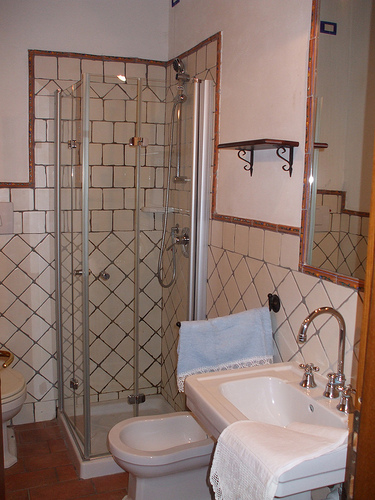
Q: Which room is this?
A: It is a bathroom.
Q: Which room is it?
A: It is a bathroom.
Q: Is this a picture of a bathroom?
A: Yes, it is showing a bathroom.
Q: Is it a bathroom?
A: Yes, it is a bathroom.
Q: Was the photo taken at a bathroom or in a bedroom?
A: It was taken at a bathroom.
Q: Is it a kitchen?
A: No, it is a bathroom.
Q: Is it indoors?
A: Yes, it is indoors.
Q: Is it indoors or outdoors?
A: It is indoors.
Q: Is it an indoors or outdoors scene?
A: It is indoors.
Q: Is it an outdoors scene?
A: No, it is indoors.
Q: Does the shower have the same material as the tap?
A: No, the shower is made of glass and the tap is made of metal.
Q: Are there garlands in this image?
A: No, there are no garlands.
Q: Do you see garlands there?
A: No, there are no garlands.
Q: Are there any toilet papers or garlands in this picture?
A: No, there are no garlands or toilet papers.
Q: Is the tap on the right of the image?
A: Yes, the tap is on the right of the image.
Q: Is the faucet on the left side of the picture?
A: No, the faucet is on the right of the image.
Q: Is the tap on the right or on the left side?
A: The tap is on the right of the image.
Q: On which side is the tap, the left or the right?
A: The tap is on the right of the image.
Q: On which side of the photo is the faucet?
A: The faucet is on the right of the image.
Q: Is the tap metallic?
A: Yes, the tap is metallic.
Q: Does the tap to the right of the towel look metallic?
A: Yes, the tap is metallic.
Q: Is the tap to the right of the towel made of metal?
A: Yes, the tap is made of metal.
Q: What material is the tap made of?
A: The tap is made of metal.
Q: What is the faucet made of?
A: The tap is made of metal.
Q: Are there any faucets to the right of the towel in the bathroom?
A: Yes, there is a faucet to the right of the towel.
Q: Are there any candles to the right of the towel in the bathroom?
A: No, there is a faucet to the right of the towel.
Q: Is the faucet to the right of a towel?
A: Yes, the faucet is to the right of a towel.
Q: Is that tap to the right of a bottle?
A: No, the tap is to the right of a towel.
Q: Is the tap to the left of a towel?
A: No, the tap is to the right of a towel.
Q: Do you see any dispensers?
A: No, there are no dispensers.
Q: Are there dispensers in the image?
A: No, there are no dispensers.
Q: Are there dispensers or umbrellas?
A: No, there are no dispensers or umbrellas.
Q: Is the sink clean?
A: Yes, the sink is clean.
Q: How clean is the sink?
A: The sink is clean.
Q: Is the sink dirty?
A: No, the sink is clean.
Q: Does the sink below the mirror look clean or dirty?
A: The sink is clean.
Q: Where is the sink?
A: The sink is in the bathroom.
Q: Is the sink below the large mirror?
A: Yes, the sink is below the mirror.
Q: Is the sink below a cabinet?
A: No, the sink is below the mirror.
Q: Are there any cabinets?
A: No, there are no cabinets.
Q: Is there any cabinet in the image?
A: No, there are no cabinets.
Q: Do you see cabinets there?
A: No, there are no cabinets.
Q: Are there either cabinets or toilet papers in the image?
A: No, there are no cabinets or toilet papers.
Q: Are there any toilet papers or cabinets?
A: No, there are no cabinets or toilet papers.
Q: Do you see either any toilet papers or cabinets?
A: No, there are no cabinets or toilet papers.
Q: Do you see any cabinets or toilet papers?
A: No, there are no cabinets or toilet papers.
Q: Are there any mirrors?
A: Yes, there is a mirror.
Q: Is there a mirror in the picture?
A: Yes, there is a mirror.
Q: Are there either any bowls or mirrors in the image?
A: Yes, there is a mirror.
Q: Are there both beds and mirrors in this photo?
A: No, there is a mirror but no beds.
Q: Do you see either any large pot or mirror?
A: Yes, there is a large mirror.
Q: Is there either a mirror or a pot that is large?
A: Yes, the mirror is large.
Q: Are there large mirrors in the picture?
A: Yes, there is a large mirror.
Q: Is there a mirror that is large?
A: Yes, there is a mirror that is large.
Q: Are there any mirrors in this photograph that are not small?
A: Yes, there is a large mirror.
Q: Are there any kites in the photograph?
A: No, there are no kites.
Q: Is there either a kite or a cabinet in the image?
A: No, there are no kites or cabinets.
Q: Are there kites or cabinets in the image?
A: No, there are no kites or cabinets.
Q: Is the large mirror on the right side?
A: Yes, the mirror is on the right of the image.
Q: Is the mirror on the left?
A: No, the mirror is on the right of the image.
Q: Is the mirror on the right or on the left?
A: The mirror is on the right of the image.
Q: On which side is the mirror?
A: The mirror is on the right of the image.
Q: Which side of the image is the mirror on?
A: The mirror is on the right of the image.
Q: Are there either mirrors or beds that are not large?
A: No, there is a mirror but it is large.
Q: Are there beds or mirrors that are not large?
A: No, there is a mirror but it is large.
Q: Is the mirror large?
A: Yes, the mirror is large.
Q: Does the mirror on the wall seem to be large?
A: Yes, the mirror is large.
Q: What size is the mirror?
A: The mirror is large.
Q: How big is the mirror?
A: The mirror is large.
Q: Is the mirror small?
A: No, the mirror is large.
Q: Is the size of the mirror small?
A: No, the mirror is large.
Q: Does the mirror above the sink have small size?
A: No, the mirror is large.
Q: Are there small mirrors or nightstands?
A: No, there is a mirror but it is large.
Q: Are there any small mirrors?
A: No, there is a mirror but it is large.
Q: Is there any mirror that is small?
A: No, there is a mirror but it is large.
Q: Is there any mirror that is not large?
A: No, there is a mirror but it is large.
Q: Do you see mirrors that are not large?
A: No, there is a mirror but it is large.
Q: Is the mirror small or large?
A: The mirror is large.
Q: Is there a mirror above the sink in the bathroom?
A: Yes, there is a mirror above the sink.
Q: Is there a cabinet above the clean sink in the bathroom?
A: No, there is a mirror above the sink.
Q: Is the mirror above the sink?
A: Yes, the mirror is above the sink.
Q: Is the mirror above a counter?
A: No, the mirror is above the sink.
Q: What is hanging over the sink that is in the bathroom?
A: The mirror is hanging over the sink.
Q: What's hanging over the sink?
A: The mirror is hanging over the sink.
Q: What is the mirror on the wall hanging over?
A: The mirror is hanging over the sink.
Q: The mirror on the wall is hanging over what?
A: The mirror is hanging over the sink.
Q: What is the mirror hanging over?
A: The mirror is hanging over the sink.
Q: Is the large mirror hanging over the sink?
A: Yes, the mirror is hanging over the sink.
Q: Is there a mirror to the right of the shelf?
A: Yes, there is a mirror to the right of the shelf.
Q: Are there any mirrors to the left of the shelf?
A: No, the mirror is to the right of the shelf.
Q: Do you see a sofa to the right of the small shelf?
A: No, there is a mirror to the right of the shelf.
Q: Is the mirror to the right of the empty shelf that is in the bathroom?
A: Yes, the mirror is to the right of the shelf.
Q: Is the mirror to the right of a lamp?
A: No, the mirror is to the right of the shelf.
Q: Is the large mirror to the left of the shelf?
A: No, the mirror is to the right of the shelf.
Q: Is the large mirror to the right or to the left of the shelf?
A: The mirror is to the right of the shelf.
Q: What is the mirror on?
A: The mirror is on the wall.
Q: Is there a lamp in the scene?
A: No, there are no lamps.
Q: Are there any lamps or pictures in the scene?
A: No, there are no lamps or pictures.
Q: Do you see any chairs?
A: No, there are no chairs.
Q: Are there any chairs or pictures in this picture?
A: No, there are no chairs or pictures.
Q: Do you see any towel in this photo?
A: Yes, there is a towel.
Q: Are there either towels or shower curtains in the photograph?
A: Yes, there is a towel.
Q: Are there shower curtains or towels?
A: Yes, there is a towel.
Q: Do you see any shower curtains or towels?
A: Yes, there is a towel.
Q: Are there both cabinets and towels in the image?
A: No, there is a towel but no cabinets.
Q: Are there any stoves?
A: No, there are no stoves.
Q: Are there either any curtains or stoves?
A: No, there are no stoves or curtains.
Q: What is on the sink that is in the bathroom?
A: The towel is on the sink.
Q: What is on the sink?
A: The towel is on the sink.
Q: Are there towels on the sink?
A: Yes, there is a towel on the sink.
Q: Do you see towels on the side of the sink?
A: Yes, there is a towel on the side of the sink.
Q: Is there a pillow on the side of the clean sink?
A: No, there is a towel on the side of the sink.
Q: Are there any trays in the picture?
A: No, there are no trays.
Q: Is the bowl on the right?
A: No, the bowl is on the left of the image.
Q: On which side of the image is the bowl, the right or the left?
A: The bowl is on the left of the image.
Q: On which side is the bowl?
A: The bowl is on the left of the image.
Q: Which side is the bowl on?
A: The bowl is on the left of the image.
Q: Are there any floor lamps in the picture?
A: No, there are no floor lamps.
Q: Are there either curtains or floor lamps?
A: No, there are no floor lamps or curtains.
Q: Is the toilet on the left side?
A: Yes, the toilet is on the left of the image.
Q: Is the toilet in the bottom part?
A: Yes, the toilet is in the bottom of the image.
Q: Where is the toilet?
A: The toilet is in the bathroom.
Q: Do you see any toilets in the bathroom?
A: Yes, there is a toilet in the bathroom.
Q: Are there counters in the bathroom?
A: No, there is a toilet in the bathroom.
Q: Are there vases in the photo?
A: No, there are no vases.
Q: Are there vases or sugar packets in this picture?
A: No, there are no vases or sugar packets.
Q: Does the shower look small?
A: Yes, the shower is small.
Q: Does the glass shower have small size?
A: Yes, the shower is small.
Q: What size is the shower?
A: The shower is small.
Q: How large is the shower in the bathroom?
A: The shower is small.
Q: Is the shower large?
A: No, the shower is small.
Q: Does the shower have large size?
A: No, the shower is small.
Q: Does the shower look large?
A: No, the shower is small.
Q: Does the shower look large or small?
A: The shower is small.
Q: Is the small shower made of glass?
A: Yes, the shower is made of glass.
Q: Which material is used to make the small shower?
A: The shower is made of glass.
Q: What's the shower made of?
A: The shower is made of glass.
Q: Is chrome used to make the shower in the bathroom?
A: No, the shower is made of glass.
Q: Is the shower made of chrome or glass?
A: The shower is made of glass.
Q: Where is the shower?
A: The shower is in the bathroom.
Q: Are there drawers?
A: No, there are no drawers.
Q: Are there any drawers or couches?
A: No, there are no drawers or couches.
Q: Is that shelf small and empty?
A: Yes, the shelf is small and empty.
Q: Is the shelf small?
A: Yes, the shelf is small.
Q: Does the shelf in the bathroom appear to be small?
A: Yes, the shelf is small.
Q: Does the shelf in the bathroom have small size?
A: Yes, the shelf is small.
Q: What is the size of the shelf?
A: The shelf is small.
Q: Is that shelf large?
A: No, the shelf is small.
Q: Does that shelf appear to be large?
A: No, the shelf is small.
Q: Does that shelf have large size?
A: No, the shelf is small.